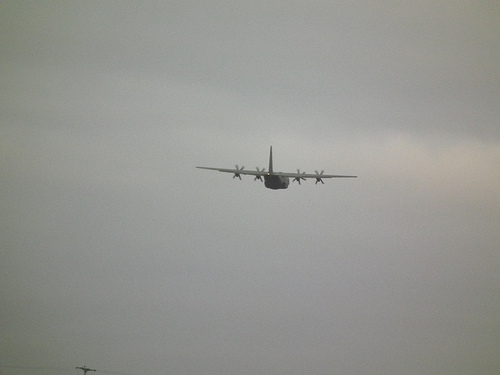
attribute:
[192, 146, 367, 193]
plane — circling airport, waiting to land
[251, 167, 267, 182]
propeller — engine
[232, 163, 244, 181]
propeller — four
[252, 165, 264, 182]
propeller — four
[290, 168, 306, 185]
propeller — four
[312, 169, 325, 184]
propeller — four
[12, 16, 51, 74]
sky — dark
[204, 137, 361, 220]
plane — in the clouds, taking off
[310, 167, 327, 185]
engine — propeller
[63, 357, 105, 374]
object — dark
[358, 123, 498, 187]
cloud — white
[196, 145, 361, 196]
plane — gray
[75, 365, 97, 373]
electrical pole — on ground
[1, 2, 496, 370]
sky — high, gray overcast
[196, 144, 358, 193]
aircraft — c130 hercules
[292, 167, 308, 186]
propeller — engine